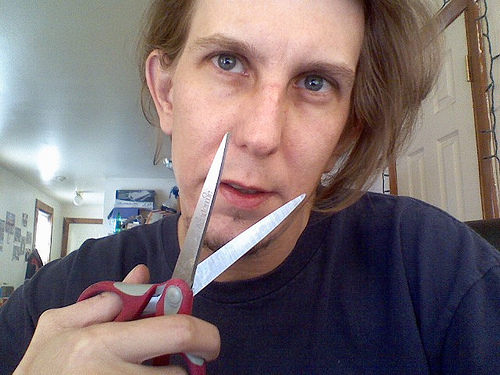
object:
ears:
[144, 50, 175, 136]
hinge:
[464, 54, 472, 81]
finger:
[33, 264, 151, 328]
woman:
[0, 0, 495, 372]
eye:
[207, 51, 250, 78]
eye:
[295, 73, 341, 93]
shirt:
[8, 192, 497, 372]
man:
[0, 0, 499, 373]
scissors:
[74, 129, 307, 375]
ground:
[394, 98, 436, 150]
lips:
[216, 179, 276, 209]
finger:
[105, 312, 222, 363]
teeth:
[231, 183, 256, 194]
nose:
[235, 65, 288, 156]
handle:
[75, 278, 205, 374]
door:
[380, 9, 484, 222]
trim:
[465, 5, 498, 222]